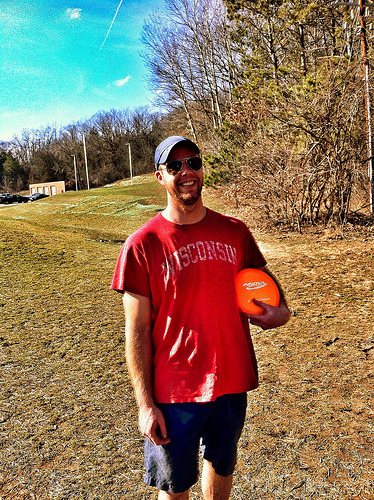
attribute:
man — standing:
[106, 126, 286, 497]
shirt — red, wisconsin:
[112, 200, 276, 401]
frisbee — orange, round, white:
[223, 261, 297, 322]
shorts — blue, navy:
[139, 386, 245, 494]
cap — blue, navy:
[151, 126, 201, 166]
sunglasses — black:
[154, 157, 208, 175]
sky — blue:
[2, 2, 191, 125]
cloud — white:
[107, 68, 140, 92]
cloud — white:
[60, 5, 92, 35]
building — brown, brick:
[20, 149, 70, 204]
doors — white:
[32, 186, 57, 196]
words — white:
[239, 278, 266, 291]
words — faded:
[159, 234, 241, 285]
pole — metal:
[64, 147, 83, 196]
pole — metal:
[80, 124, 108, 195]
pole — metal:
[115, 134, 140, 183]